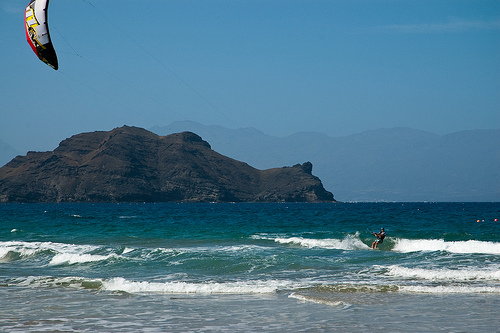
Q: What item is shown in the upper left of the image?
A: Kite.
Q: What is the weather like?
A: Clear.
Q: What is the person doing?
A: Kite sailing.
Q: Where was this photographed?
A: Ocean.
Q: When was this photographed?
A: Daytime.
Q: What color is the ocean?
A: Blue.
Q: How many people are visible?
A: One.